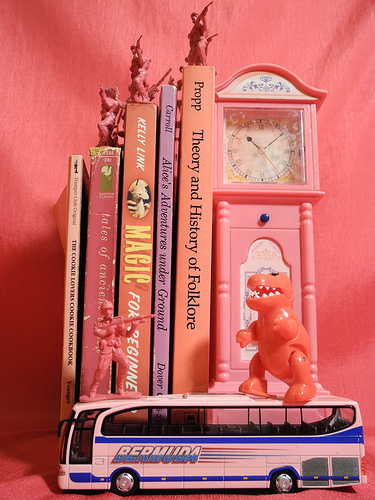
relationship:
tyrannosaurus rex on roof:
[234, 266, 329, 408] [68, 393, 359, 414]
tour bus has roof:
[46, 385, 374, 500] [68, 393, 359, 414]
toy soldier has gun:
[174, 0, 225, 67] [189, 2, 213, 34]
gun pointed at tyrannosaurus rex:
[189, 2, 213, 34] [234, 266, 329, 408]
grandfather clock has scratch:
[204, 55, 334, 397] [235, 107, 252, 126]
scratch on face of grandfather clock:
[235, 107, 252, 126] [204, 55, 334, 397]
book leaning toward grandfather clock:
[167, 58, 219, 398] [204, 55, 334, 397]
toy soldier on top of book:
[174, 0, 225, 67] [167, 58, 219, 398]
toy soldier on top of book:
[121, 32, 154, 107] [111, 96, 159, 426]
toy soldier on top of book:
[90, 77, 126, 150] [73, 142, 125, 402]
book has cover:
[73, 142, 125, 402] [73, 141, 123, 456]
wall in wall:
[2, 2, 374, 432] [1, 2, 375, 500]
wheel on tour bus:
[105, 468, 144, 499] [46, 385, 374, 500]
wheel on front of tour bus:
[105, 468, 144, 499] [46, 385, 374, 500]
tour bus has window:
[46, 385, 374, 500] [98, 404, 150, 439]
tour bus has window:
[46, 385, 374, 500] [147, 407, 171, 440]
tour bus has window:
[46, 385, 374, 500] [169, 406, 207, 438]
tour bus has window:
[46, 385, 374, 500] [204, 407, 262, 440]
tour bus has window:
[46, 385, 374, 500] [259, 406, 287, 439]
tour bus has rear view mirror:
[46, 385, 374, 500] [52, 419, 69, 442]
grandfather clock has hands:
[204, 55, 334, 397] [239, 130, 292, 156]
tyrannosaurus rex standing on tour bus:
[234, 266, 329, 408] [46, 385, 374, 500]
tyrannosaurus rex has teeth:
[234, 266, 329, 408] [243, 281, 284, 306]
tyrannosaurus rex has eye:
[234, 266, 329, 408] [264, 269, 284, 281]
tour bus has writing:
[46, 385, 374, 500] [108, 442, 205, 473]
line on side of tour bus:
[92, 434, 368, 446] [46, 385, 374, 500]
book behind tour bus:
[52, 149, 88, 437] [46, 385, 374, 500]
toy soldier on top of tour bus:
[174, 0, 225, 67] [46, 385, 374, 500]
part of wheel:
[114, 470, 137, 485] [105, 468, 144, 499]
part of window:
[204, 407, 224, 423] [204, 407, 262, 440]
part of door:
[83, 440, 97, 458] [67, 419, 95, 481]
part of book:
[158, 80, 180, 149] [147, 80, 185, 426]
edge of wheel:
[112, 479, 121, 498] [105, 468, 144, 499]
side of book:
[83, 144, 125, 432] [73, 142, 125, 402]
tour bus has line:
[46, 385, 374, 500] [92, 434, 368, 446]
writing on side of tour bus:
[108, 442, 205, 473] [46, 385, 374, 500]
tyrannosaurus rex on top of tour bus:
[234, 266, 329, 408] [46, 385, 374, 500]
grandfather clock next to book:
[204, 55, 334, 397] [167, 58, 219, 398]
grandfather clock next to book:
[204, 55, 334, 397] [147, 80, 185, 426]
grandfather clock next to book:
[204, 55, 334, 397] [111, 96, 159, 426]